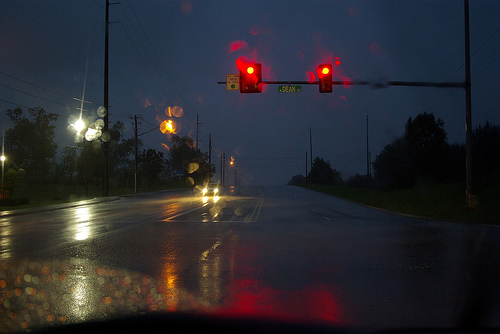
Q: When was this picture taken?
A: Nighttime.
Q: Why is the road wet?
A: Rained.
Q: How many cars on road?
A: One.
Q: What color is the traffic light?
A: Red.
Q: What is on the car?
A: Headlights.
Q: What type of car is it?
A: No indication.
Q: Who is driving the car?
A: No indication.